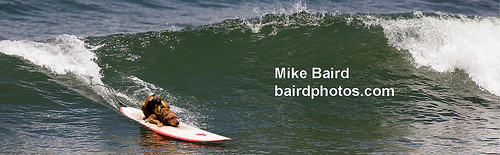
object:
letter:
[272, 67, 284, 78]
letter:
[285, 67, 288, 79]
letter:
[341, 68, 349, 80]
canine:
[139, 94, 182, 127]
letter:
[310, 67, 322, 79]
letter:
[321, 69, 331, 78]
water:
[173, 45, 243, 104]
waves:
[311, 2, 496, 85]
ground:
[398, 92, 448, 130]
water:
[335, 129, 496, 154]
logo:
[195, 132, 207, 137]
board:
[118, 106, 234, 152]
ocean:
[6, 3, 496, 150]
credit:
[274, 67, 396, 100]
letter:
[323, 69, 330, 79]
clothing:
[146, 94, 162, 115]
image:
[6, 2, 498, 151]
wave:
[3, 13, 329, 77]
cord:
[86, 76, 127, 107]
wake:
[33, 32, 102, 92]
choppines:
[0, 0, 500, 155]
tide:
[1, 1, 496, 56]